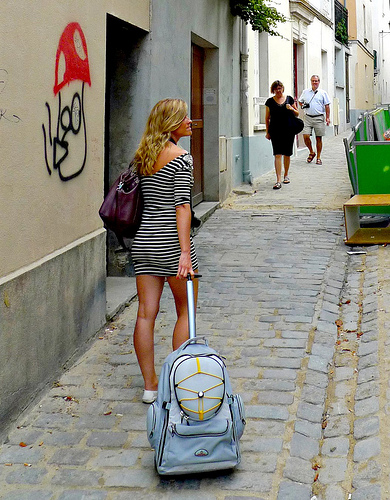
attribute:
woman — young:
[98, 97, 200, 402]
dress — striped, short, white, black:
[132, 155, 199, 278]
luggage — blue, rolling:
[146, 273, 245, 477]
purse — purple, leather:
[98, 153, 144, 235]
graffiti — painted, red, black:
[43, 21, 88, 180]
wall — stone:
[3, 3, 149, 443]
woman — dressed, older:
[264, 81, 304, 191]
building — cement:
[149, 1, 232, 223]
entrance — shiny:
[191, 42, 205, 207]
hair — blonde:
[136, 98, 186, 176]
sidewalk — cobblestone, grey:
[5, 204, 383, 495]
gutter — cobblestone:
[280, 240, 377, 498]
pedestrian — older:
[299, 74, 331, 166]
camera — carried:
[304, 91, 316, 111]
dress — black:
[265, 95, 297, 156]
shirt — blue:
[297, 88, 330, 117]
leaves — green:
[229, 0, 288, 40]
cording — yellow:
[175, 358, 225, 419]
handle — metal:
[182, 272, 201, 345]